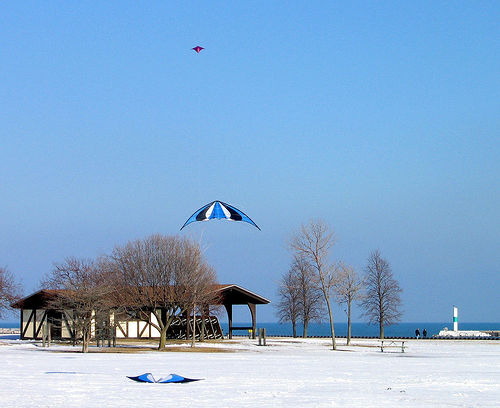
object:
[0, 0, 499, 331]
sky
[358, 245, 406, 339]
tree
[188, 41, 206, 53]
kite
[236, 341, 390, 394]
ground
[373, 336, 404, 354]
table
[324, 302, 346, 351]
stem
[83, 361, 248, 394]
ground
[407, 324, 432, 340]
people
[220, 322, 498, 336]
water